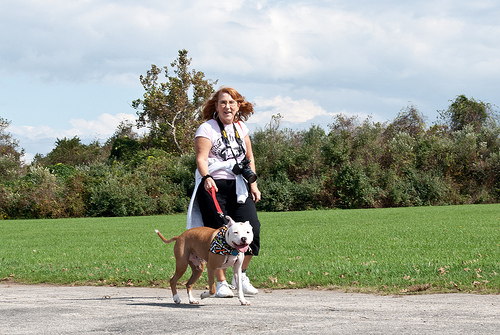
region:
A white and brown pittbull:
[155, 222, 253, 305]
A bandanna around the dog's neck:
[208, 228, 238, 258]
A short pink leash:
[207, 184, 224, 216]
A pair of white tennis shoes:
[210, 274, 258, 298]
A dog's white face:
[227, 216, 252, 253]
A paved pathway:
[0, 280, 496, 333]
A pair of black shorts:
[197, 179, 264, 256]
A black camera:
[232, 154, 258, 183]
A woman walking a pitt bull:
[153, 86, 258, 305]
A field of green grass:
[0, 195, 495, 292]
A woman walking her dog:
[150, 80, 276, 317]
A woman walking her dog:
[145, 76, 265, 311]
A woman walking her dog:
[150, 81, 267, 311]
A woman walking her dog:
[140, 75, 265, 310]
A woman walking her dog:
[146, 81, 277, 311]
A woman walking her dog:
[142, 81, 272, 311]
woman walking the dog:
[154, 86, 263, 308]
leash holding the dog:
[205, 183, 232, 218]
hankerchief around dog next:
[208, 225, 228, 254]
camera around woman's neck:
[221, 143, 255, 180]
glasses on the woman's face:
[218, 99, 240, 107]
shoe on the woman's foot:
[217, 278, 232, 295]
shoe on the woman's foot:
[234, 271, 254, 295]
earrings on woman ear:
[208, 108, 218, 116]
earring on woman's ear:
[238, 108, 242, 120]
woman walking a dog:
[151, 80, 293, 305]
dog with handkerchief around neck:
[204, 219, 273, 261]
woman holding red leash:
[197, 165, 237, 230]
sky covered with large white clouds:
[39, 18, 477, 129]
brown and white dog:
[145, 210, 280, 306]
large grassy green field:
[25, 195, 495, 267]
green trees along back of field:
[22, 108, 474, 204]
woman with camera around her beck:
[208, 89, 266, 184]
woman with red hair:
[192, 87, 264, 129]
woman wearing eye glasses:
[205, 90, 260, 134]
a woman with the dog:
[150, 71, 289, 295]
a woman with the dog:
[120, 79, 300, 291]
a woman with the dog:
[152, 74, 302, 294]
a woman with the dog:
[133, 63, 285, 285]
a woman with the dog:
[105, 54, 297, 321]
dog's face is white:
[221, 207, 271, 257]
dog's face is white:
[205, 200, 280, 270]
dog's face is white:
[210, 209, 272, 271]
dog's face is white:
[206, 211, 287, 270]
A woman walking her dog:
[145, 70, 285, 315]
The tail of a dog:
[140, 212, 185, 254]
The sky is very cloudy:
[0, 0, 495, 166]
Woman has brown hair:
[191, 80, 257, 130]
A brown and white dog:
[145, 205, 265, 315]